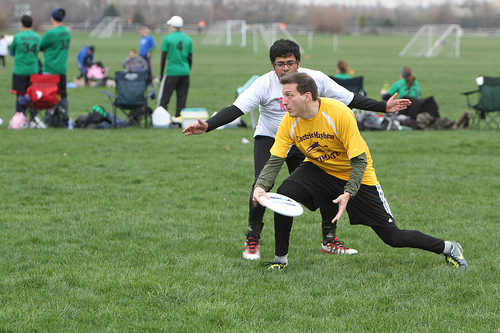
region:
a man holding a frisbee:
[226, 76, 375, 264]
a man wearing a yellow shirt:
[261, 80, 347, 179]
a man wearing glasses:
[265, 28, 302, 83]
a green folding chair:
[458, 65, 498, 125]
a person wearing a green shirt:
[158, 13, 191, 112]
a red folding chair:
[18, 70, 54, 120]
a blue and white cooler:
[152, 106, 168, 132]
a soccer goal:
[391, 16, 468, 71]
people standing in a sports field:
[2, 5, 217, 138]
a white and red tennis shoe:
[231, 225, 270, 271]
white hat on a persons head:
[161, 12, 191, 34]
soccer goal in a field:
[388, 17, 478, 67]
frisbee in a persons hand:
[241, 178, 311, 224]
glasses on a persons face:
[267, 54, 304, 74]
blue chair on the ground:
[98, 63, 162, 135]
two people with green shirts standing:
[4, 4, 84, 136]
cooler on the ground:
[172, 103, 215, 136]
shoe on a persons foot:
[432, 230, 480, 283]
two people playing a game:
[165, 25, 482, 306]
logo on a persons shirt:
[289, 126, 347, 171]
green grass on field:
[41, 199, 246, 281]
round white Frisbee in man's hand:
[235, 186, 324, 234]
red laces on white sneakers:
[315, 235, 362, 259]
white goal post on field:
[393, 9, 498, 71]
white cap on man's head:
[156, 13, 188, 28]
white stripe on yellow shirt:
[320, 108, 340, 164]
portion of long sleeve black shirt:
[206, 93, 263, 160]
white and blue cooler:
[138, 98, 189, 150]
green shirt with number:
[146, 26, 208, 92]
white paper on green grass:
[228, 123, 251, 150]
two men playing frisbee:
[175, 31, 474, 275]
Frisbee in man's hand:
[243, 178, 307, 218]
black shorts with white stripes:
[284, 153, 398, 229]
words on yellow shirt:
[296, 129, 335, 143]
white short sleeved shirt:
[224, 60, 359, 150]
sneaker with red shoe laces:
[236, 232, 262, 277]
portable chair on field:
[107, 58, 154, 130]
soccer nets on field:
[401, 14, 470, 62]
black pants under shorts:
[366, 215, 443, 260]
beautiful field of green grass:
[19, 130, 219, 305]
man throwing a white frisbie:
[251, 72, 418, 257]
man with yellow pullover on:
[261, 88, 389, 193]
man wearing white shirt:
[211, 50, 367, 151]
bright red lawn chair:
[3, 68, 85, 144]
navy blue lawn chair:
[100, 57, 158, 139]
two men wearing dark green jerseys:
[0, 23, 89, 78]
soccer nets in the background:
[208, 14, 473, 38]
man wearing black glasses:
[232, 40, 349, 105]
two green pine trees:
[88, 8, 150, 32]